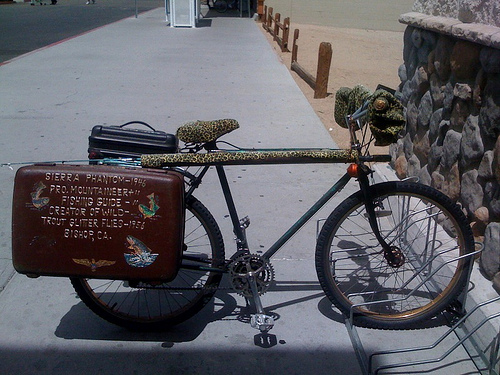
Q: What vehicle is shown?
A: Bicycle.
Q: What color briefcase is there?
A: Brown.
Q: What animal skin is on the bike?
A: Cheetah.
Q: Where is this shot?
A: Sidewalk.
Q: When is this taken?
A: Daytime.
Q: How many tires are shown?
A: 2.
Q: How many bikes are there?
A: 1.